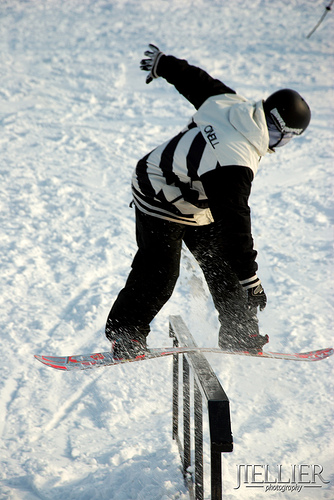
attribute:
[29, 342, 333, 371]
snowboard — middle,  small, small, red, grey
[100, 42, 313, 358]
person — leaning, snowboarding, balancing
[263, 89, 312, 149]
helmet — dark, black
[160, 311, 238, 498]
railing — black, metal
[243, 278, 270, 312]
glove — black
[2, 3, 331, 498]
snow — light,  ground, white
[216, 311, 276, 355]
boot — black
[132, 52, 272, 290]
jacket — white, large, black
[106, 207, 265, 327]
pants — black, dark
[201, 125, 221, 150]
logo — black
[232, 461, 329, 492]
label —  photographer's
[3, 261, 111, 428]
tracks — from ski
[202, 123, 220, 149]
wording —  onell